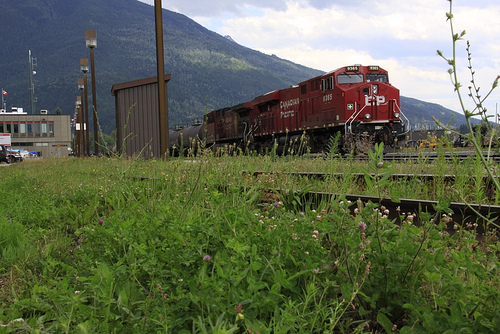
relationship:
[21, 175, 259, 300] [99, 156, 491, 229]
grass surrounding tracks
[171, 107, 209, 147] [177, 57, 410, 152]
truck on train